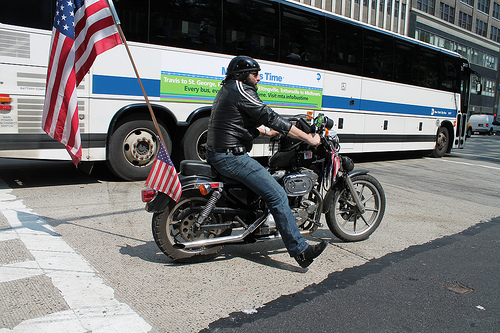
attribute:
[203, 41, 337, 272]
man — white, tall, old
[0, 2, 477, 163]
bus — white, big, moving, wide, blue, black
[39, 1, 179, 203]
flag — red, blue, big, american, large, small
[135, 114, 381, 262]
bike — black